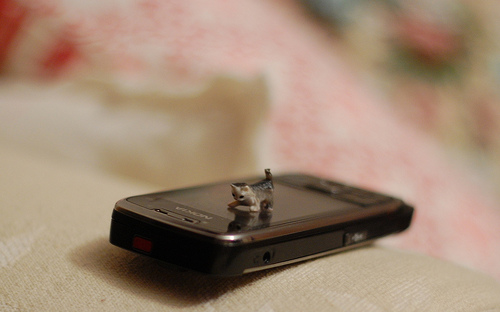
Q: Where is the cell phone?
A: Arm of a chair.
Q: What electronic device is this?
A: Cell phone.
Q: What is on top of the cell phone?
A: Cat figurine.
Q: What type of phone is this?
A: Mobile.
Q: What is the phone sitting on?
A: Arm of a chair.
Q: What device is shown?
A: Cell phone.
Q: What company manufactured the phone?
A: Nokia.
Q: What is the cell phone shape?
A: Rectangle.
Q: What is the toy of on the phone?
A: Cat.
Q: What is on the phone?
A: Toy.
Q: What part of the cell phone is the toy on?
A: Screen.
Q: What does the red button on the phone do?
A: Power button.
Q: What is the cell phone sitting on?
A: Back of couch.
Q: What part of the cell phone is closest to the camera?
A: Top.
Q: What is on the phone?
A: The cat.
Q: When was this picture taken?
A: After the cat was put on the phone.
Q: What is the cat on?
A: The phone.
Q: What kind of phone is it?
A: A cell phone.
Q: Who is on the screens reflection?
A: The cat.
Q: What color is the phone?
A: Black.